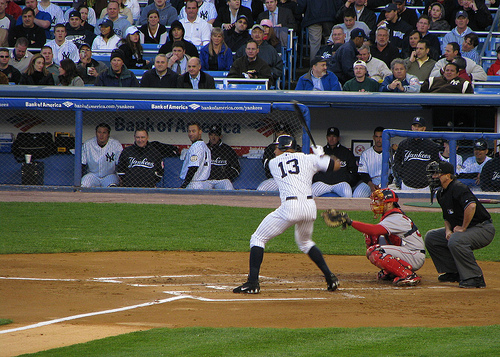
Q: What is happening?
A: A baseball game.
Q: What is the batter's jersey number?
A: Thirteen.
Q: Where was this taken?
A: A baseball stadium.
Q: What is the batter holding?
A: A bat.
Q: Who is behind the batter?
A: The catcher and umpire.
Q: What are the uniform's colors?
A: White and black.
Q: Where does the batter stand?
A: On the dirt of home base.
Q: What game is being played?
A: Baseball.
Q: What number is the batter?
A: 13.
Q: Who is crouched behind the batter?
A: The catcher.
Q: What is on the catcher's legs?
A: Shin guards.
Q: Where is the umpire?
A: Behind the catcher.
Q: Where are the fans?
A: In the stands.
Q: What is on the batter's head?
A: A batting helmet.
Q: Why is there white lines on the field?
A: To mark the batters boxes and baselines.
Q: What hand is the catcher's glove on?
A: Left.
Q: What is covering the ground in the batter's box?
A: Dirt.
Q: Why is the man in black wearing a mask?
A: For protection.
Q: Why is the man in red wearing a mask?
A: For protection.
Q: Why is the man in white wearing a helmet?
A: For protection.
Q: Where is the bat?
A: In the man in white's hands.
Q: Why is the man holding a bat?
A: To hit the ball.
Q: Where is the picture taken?
A: Baseball field.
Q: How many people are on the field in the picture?
A: Three.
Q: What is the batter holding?
A: A bat.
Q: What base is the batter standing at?
A: Home base.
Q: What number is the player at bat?
A: 13.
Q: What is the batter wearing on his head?
A: A helmet.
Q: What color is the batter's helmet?
A: Black.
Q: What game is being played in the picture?
A: Baseball.